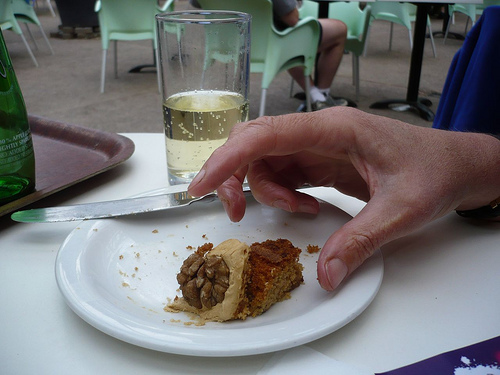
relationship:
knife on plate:
[9, 180, 315, 224] [59, 245, 396, 305]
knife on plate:
[9, 177, 315, 222] [51, 176, 387, 362]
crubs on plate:
[111, 224, 209, 290] [51, 176, 387, 362]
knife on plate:
[9, 180, 315, 224] [51, 182, 384, 359]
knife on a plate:
[9, 180, 315, 224] [51, 176, 387, 362]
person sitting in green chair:
[274, 2, 349, 112] [92, 3, 164, 91]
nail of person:
[319, 254, 350, 290] [190, 2, 484, 285]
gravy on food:
[220, 233, 246, 310] [168, 226, 313, 329]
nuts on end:
[179, 253, 226, 308] [166, 243, 246, 321]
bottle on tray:
[0, 26, 37, 205] [0, 112, 137, 235]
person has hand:
[183, 7, 499, 293] [186, 103, 473, 293]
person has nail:
[189, 0, 358, 116] [318, 231, 364, 301]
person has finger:
[183, 7, 499, 293] [184, 122, 268, 204]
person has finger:
[183, 7, 499, 293] [216, 170, 250, 224]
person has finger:
[183, 7, 499, 293] [247, 165, 326, 223]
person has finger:
[183, 7, 499, 293] [212, 185, 256, 227]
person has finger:
[177, 99, 249, 151] [248, 162, 294, 212]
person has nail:
[161, 81, 498, 281] [217, 191, 251, 223]